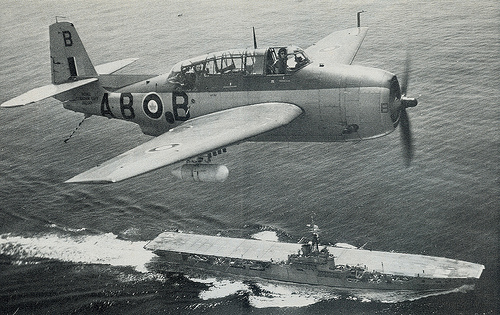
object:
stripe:
[67, 57, 78, 76]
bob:
[120, 91, 196, 124]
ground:
[294, 130, 457, 232]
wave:
[0, 223, 155, 274]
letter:
[172, 91, 191, 122]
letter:
[142, 92, 165, 119]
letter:
[119, 92, 136, 120]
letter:
[100, 92, 116, 117]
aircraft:
[0, 10, 417, 184]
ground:
[375, 252, 411, 280]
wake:
[0, 232, 152, 274]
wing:
[301, 25, 370, 65]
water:
[0, 0, 500, 315]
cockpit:
[168, 46, 312, 77]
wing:
[65, 100, 302, 185]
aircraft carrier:
[143, 231, 484, 292]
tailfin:
[0, 16, 139, 114]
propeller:
[395, 46, 417, 167]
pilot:
[267, 48, 291, 75]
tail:
[1, 16, 136, 126]